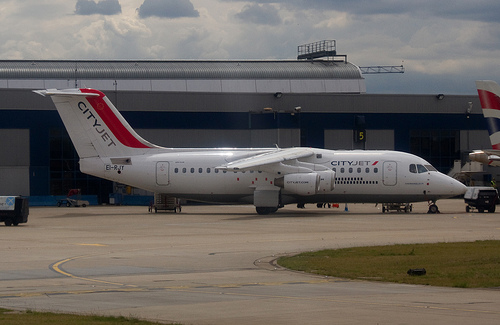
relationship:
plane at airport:
[33, 86, 475, 215] [0, 37, 499, 210]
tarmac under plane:
[2, 201, 500, 323] [33, 86, 475, 215]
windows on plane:
[174, 159, 438, 179] [33, 86, 475, 215]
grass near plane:
[279, 239, 499, 298] [33, 86, 475, 215]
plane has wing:
[33, 86, 475, 215] [214, 142, 316, 171]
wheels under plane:
[247, 201, 442, 214] [33, 86, 475, 215]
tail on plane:
[26, 80, 156, 191] [33, 86, 475, 215]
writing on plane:
[76, 100, 120, 150] [33, 86, 475, 215]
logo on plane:
[327, 157, 381, 167] [33, 86, 475, 215]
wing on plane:
[214, 142, 316, 171] [33, 86, 475, 215]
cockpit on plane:
[404, 153, 442, 184] [33, 86, 475, 215]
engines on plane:
[269, 163, 337, 202] [33, 86, 475, 215]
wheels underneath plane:
[247, 201, 442, 214] [33, 86, 475, 215]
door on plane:
[377, 159, 402, 192] [33, 86, 475, 215]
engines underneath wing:
[269, 163, 337, 202] [214, 142, 316, 171]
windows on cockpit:
[404, 160, 439, 174] [404, 153, 442, 184]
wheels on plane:
[247, 201, 442, 214] [33, 86, 475, 215]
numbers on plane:
[99, 162, 132, 172] [33, 86, 475, 215]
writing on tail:
[76, 100, 120, 150] [26, 80, 156, 191]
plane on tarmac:
[33, 86, 475, 215] [2, 201, 500, 323]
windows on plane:
[404, 160, 439, 174] [33, 86, 475, 215]